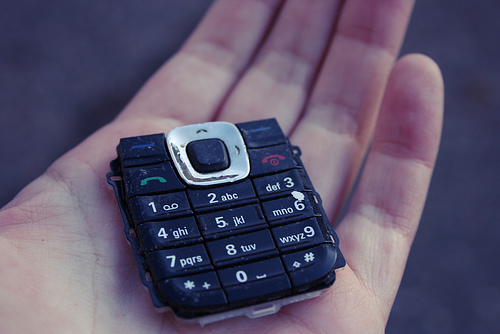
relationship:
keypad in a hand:
[120, 125, 338, 293] [8, 2, 446, 333]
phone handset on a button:
[139, 175, 169, 185] [125, 163, 179, 191]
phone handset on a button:
[261, 152, 287, 165] [245, 146, 298, 176]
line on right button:
[247, 125, 277, 136] [236, 115, 295, 148]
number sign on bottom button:
[302, 250, 319, 264] [283, 239, 335, 285]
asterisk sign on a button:
[181, 276, 199, 294] [164, 275, 230, 314]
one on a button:
[146, 197, 159, 217] [127, 194, 190, 217]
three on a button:
[284, 174, 295, 190] [250, 173, 313, 198]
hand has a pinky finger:
[8, 2, 446, 333] [350, 50, 459, 288]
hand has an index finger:
[8, 2, 446, 333] [140, 0, 256, 127]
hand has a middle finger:
[8, 2, 446, 333] [225, 5, 326, 118]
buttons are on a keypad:
[146, 192, 329, 283] [120, 125, 338, 293]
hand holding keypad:
[8, 2, 446, 333] [120, 125, 338, 293]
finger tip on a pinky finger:
[386, 50, 447, 90] [350, 50, 459, 288]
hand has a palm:
[8, 2, 446, 333] [14, 183, 154, 333]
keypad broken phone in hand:
[120, 125, 338, 293] [8, 2, 446, 333]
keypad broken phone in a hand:
[120, 125, 338, 293] [8, 2, 446, 333]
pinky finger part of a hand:
[350, 50, 459, 288] [8, 2, 446, 333]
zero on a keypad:
[233, 268, 249, 286] [120, 125, 338, 293]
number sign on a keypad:
[303, 252, 315, 262] [120, 125, 338, 293]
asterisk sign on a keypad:
[183, 279, 195, 289] [120, 125, 338, 293]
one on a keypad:
[146, 197, 159, 217] [120, 125, 338, 293]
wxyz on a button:
[275, 232, 308, 247] [275, 225, 329, 248]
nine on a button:
[302, 224, 320, 241] [275, 225, 329, 248]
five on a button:
[213, 213, 233, 235] [197, 200, 259, 236]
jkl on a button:
[230, 213, 247, 230] [197, 200, 259, 236]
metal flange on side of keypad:
[106, 163, 161, 316] [120, 125, 338, 293]